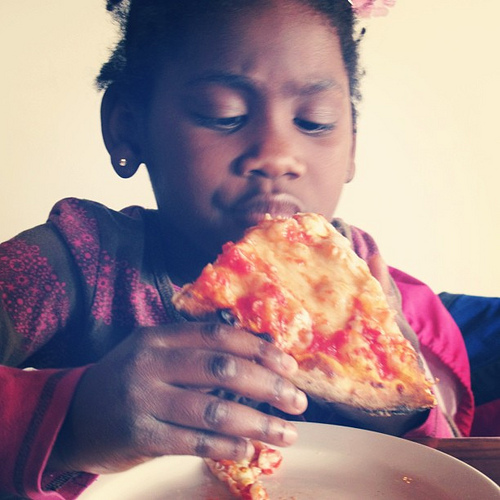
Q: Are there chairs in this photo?
A: No, there are no chairs.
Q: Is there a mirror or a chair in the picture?
A: No, there are no chairs or mirrors.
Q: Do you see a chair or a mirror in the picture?
A: No, there are no chairs or mirrors.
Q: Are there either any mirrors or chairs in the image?
A: No, there are no chairs or mirrors.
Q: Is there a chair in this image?
A: No, there are no chairs.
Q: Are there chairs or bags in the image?
A: No, there are no chairs or bags.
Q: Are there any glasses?
A: No, there are no glasses.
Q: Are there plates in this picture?
A: Yes, there is a plate.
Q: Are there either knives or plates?
A: Yes, there is a plate.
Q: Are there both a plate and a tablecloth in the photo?
A: No, there is a plate but no tablecloths.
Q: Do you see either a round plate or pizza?
A: Yes, there is a round plate.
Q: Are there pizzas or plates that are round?
A: Yes, the plate is round.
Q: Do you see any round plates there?
A: Yes, there is a round plate.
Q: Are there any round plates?
A: Yes, there is a round plate.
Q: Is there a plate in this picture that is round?
A: Yes, there is a plate that is round.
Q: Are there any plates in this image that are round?
A: Yes, there is a plate that is round.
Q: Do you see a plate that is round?
A: Yes, there is a plate that is round.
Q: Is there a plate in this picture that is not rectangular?
A: Yes, there is a round plate.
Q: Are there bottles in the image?
A: No, there are no bottles.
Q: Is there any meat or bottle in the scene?
A: No, there are no bottles or meat.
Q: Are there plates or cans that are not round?
A: No, there is a plate but it is round.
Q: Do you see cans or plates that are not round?
A: No, there is a plate but it is round.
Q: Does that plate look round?
A: Yes, the plate is round.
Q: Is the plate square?
A: No, the plate is round.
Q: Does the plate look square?
A: No, the plate is round.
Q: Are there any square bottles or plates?
A: No, there is a plate but it is round.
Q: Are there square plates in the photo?
A: No, there is a plate but it is round.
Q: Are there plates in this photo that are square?
A: No, there is a plate but it is round.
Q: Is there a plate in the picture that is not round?
A: No, there is a plate but it is round.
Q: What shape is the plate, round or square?
A: The plate is round.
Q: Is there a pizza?
A: Yes, there is a pizza.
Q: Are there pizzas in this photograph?
A: Yes, there is a pizza.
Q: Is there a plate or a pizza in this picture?
A: Yes, there is a pizza.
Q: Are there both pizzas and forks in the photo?
A: No, there is a pizza but no forks.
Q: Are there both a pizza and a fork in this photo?
A: No, there is a pizza but no forks.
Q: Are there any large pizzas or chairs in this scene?
A: Yes, there is a large pizza.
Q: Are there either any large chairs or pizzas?
A: Yes, there is a large pizza.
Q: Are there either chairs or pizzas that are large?
A: Yes, the pizza is large.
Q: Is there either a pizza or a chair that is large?
A: Yes, the pizza is large.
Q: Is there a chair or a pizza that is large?
A: Yes, the pizza is large.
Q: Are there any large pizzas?
A: Yes, there is a large pizza.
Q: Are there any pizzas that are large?
A: Yes, there is a pizza that is large.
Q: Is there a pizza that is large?
A: Yes, there is a pizza that is large.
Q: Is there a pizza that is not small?
A: Yes, there is a large pizza.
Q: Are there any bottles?
A: No, there are no bottles.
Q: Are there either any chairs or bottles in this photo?
A: No, there are no bottles or chairs.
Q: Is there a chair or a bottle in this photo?
A: No, there are no bottles or chairs.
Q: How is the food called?
A: The food is a pizza.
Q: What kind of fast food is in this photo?
A: The fast food is a pizza.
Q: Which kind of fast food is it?
A: The food is a pizza.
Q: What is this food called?
A: This is a pizza.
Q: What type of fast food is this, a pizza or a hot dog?
A: This is a pizza.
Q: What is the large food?
A: The food is a pizza.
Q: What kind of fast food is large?
A: The fast food is a pizza.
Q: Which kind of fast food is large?
A: The fast food is a pizza.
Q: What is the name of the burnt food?
A: The food is a pizza.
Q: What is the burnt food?
A: The food is a pizza.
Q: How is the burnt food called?
A: The food is a pizza.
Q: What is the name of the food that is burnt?
A: The food is a pizza.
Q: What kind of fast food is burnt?
A: The fast food is a pizza.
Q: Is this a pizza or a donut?
A: This is a pizza.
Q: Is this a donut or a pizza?
A: This is a pizza.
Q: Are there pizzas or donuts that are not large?
A: No, there is a pizza but it is large.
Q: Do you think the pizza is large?
A: Yes, the pizza is large.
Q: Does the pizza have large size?
A: Yes, the pizza is large.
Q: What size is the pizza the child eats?
A: The pizza is large.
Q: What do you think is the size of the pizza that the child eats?
A: The pizza is large.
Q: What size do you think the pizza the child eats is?
A: The pizza is large.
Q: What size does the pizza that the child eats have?
A: The pizza has large size.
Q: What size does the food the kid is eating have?
A: The pizza has large size.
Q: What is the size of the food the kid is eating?
A: The pizza is large.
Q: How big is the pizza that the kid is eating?
A: The pizza is large.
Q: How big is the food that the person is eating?
A: The pizza is large.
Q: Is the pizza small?
A: No, the pizza is large.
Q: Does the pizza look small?
A: No, the pizza is large.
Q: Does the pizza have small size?
A: No, the pizza is large.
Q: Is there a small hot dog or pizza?
A: No, there is a pizza but it is large.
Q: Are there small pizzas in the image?
A: No, there is a pizza but it is large.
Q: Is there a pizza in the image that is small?
A: No, there is a pizza but it is large.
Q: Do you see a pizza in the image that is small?
A: No, there is a pizza but it is large.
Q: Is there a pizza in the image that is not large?
A: No, there is a pizza but it is large.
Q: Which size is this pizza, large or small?
A: The pizza is large.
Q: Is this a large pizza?
A: Yes, this is a large pizza.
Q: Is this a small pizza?
A: No, this is a large pizza.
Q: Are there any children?
A: Yes, there is a child.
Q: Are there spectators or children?
A: Yes, there is a child.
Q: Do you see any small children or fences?
A: Yes, there is a small child.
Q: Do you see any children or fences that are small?
A: Yes, the child is small.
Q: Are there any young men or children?
A: Yes, there is a young child.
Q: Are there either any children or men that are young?
A: Yes, the child is young.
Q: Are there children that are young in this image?
A: Yes, there is a young child.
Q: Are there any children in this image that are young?
A: Yes, there is a child that is young.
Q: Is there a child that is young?
A: Yes, there is a child that is young.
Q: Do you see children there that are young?
A: Yes, there is a child that is young.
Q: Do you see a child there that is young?
A: Yes, there is a child that is young.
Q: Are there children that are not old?
A: Yes, there is an young child.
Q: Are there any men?
A: No, there are no men.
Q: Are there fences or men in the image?
A: No, there are no men or fences.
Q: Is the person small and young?
A: Yes, the child is small and young.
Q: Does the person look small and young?
A: Yes, the child is small and young.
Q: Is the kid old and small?
A: No, the kid is small but young.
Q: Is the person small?
A: Yes, the kid is small.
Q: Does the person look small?
A: Yes, the child is small.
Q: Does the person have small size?
A: Yes, the child is small.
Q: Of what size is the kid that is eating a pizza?
A: The kid is small.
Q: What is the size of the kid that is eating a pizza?
A: The kid is small.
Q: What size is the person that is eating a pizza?
A: The kid is small.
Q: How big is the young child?
A: The child is small.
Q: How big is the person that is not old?
A: The child is small.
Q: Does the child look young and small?
A: Yes, the child is young and small.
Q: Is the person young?
A: Yes, the child is young.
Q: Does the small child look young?
A: Yes, the child is young.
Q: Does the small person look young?
A: Yes, the child is young.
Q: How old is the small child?
A: The kid is young.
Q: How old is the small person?
A: The kid is young.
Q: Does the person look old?
A: No, the kid is young.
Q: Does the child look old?
A: No, the child is young.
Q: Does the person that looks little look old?
A: No, the child is young.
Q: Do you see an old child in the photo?
A: No, there is a child but he is young.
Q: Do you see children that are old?
A: No, there is a child but he is young.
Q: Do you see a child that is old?
A: No, there is a child but he is young.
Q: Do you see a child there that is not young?
A: No, there is a child but he is young.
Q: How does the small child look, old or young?
A: The child is young.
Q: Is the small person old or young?
A: The child is young.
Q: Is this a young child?
A: Yes, this is a young child.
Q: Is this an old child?
A: No, this is a young child.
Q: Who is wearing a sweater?
A: The kid is wearing a sweater.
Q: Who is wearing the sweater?
A: The kid is wearing a sweater.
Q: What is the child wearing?
A: The child is wearing a sweater.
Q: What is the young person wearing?
A: The child is wearing a sweater.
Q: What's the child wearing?
A: The child is wearing a sweater.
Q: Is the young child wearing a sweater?
A: Yes, the kid is wearing a sweater.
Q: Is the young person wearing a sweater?
A: Yes, the kid is wearing a sweater.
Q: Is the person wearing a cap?
A: No, the child is wearing a sweater.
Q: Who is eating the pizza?
A: The kid is eating the pizza.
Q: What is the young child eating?
A: The child is eating a pizza.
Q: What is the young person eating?
A: The child is eating a pizza.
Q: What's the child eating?
A: The child is eating a pizza.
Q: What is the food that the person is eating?
A: The food is a pizza.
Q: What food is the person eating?
A: The child is eating a pizza.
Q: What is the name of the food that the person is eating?
A: The food is a pizza.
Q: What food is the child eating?
A: The child is eating a pizza.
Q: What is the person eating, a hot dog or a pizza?
A: The child is eating a pizza.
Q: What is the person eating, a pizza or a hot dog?
A: The child is eating a pizza.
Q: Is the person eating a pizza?
A: Yes, the kid is eating a pizza.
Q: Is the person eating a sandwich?
A: No, the child is eating a pizza.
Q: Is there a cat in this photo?
A: No, there are no cats.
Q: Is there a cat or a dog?
A: No, there are no cats or dogs.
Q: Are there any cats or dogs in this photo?
A: No, there are no cats or dogs.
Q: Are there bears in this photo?
A: No, there are no bears.